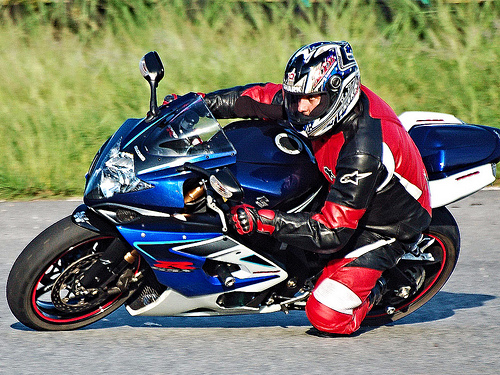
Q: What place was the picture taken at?
A: It was taken at the road.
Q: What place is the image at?
A: It is at the road.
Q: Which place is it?
A: It is a road.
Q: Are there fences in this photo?
A: No, there are no fences.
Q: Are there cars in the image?
A: No, there are no cars.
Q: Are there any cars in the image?
A: No, there are no cars.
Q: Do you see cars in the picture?
A: No, there are no cars.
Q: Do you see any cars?
A: No, there are no cars.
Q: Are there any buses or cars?
A: No, there are no cars or buses.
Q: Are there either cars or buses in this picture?
A: No, there are no cars or buses.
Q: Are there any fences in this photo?
A: No, there are no fences.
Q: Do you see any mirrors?
A: Yes, there is a mirror.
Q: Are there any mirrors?
A: Yes, there is a mirror.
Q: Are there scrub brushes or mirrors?
A: Yes, there is a mirror.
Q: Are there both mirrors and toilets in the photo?
A: No, there is a mirror but no toilets.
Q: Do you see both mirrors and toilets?
A: No, there is a mirror but no toilets.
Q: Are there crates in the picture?
A: No, there are no crates.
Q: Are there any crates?
A: No, there are no crates.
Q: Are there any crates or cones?
A: No, there are no crates or cones.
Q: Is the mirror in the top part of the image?
A: Yes, the mirror is in the top of the image.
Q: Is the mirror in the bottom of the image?
A: No, the mirror is in the top of the image.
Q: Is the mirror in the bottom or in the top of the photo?
A: The mirror is in the top of the image.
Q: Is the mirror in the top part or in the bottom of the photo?
A: The mirror is in the top of the image.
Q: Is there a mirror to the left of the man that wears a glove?
A: Yes, there is a mirror to the left of the man.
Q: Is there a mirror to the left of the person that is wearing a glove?
A: Yes, there is a mirror to the left of the man.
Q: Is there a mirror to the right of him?
A: No, the mirror is to the left of the man.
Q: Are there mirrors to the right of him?
A: No, the mirror is to the left of the man.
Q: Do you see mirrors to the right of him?
A: No, the mirror is to the left of the man.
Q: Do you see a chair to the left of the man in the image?
A: No, there is a mirror to the left of the man.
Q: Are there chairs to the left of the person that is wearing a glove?
A: No, there is a mirror to the left of the man.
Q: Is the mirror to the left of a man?
A: Yes, the mirror is to the left of a man.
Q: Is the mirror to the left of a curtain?
A: No, the mirror is to the left of a man.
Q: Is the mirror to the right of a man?
A: No, the mirror is to the left of a man.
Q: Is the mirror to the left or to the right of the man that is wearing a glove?
A: The mirror is to the left of the man.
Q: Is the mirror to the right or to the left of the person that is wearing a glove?
A: The mirror is to the left of the man.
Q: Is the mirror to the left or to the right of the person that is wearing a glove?
A: The mirror is to the left of the man.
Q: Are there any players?
A: No, there are no players.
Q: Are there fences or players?
A: No, there are no players or fences.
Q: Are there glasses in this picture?
A: No, there are no glasses.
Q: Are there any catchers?
A: No, there are no catchers.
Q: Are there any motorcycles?
A: Yes, there is a motorcycle.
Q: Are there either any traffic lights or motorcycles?
A: Yes, there is a motorcycle.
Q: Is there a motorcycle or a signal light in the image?
A: Yes, there is a motorcycle.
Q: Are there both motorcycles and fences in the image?
A: No, there is a motorcycle but no fences.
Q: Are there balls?
A: No, there are no balls.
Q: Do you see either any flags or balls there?
A: No, there are no balls or flags.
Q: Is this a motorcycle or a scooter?
A: This is a motorcycle.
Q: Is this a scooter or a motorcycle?
A: This is a motorcycle.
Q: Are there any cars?
A: No, there are no cars.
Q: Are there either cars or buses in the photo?
A: No, there are no cars or buses.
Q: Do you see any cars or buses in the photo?
A: No, there are no cars or buses.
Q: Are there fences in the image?
A: No, there are no fences.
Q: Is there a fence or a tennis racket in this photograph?
A: No, there are no fences or rackets.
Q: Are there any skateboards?
A: No, there are no skateboards.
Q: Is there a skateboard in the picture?
A: No, there are no skateboards.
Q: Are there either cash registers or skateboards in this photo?
A: No, there are no skateboards or cash registers.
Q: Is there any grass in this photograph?
A: Yes, there is grass.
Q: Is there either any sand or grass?
A: Yes, there is grass.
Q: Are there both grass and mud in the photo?
A: No, there is grass but no mud.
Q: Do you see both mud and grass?
A: No, there is grass but no mud.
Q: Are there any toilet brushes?
A: No, there are no toilet brushes.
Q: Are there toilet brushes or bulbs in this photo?
A: No, there are no toilet brushes or bulbs.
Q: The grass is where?
A: The grass is on the ground.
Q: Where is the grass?
A: The grass is on the ground.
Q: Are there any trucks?
A: No, there are no trucks.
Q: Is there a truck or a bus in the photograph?
A: No, there are no trucks or buses.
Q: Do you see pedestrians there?
A: No, there are no pedestrians.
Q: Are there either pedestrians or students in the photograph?
A: No, there are no pedestrians or students.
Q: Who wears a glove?
A: The man wears a glove.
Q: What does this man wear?
A: The man wears a glove.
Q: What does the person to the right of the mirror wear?
A: The man wears a glove.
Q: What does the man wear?
A: The man wears a glove.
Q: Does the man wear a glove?
A: Yes, the man wears a glove.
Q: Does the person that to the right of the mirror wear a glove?
A: Yes, the man wears a glove.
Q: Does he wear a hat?
A: No, the man wears a glove.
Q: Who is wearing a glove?
A: The man is wearing a glove.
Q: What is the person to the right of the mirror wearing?
A: The man is wearing a glove.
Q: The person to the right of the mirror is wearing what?
A: The man is wearing a glove.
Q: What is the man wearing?
A: The man is wearing a glove.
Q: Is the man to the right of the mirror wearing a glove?
A: Yes, the man is wearing a glove.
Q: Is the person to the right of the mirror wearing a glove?
A: Yes, the man is wearing a glove.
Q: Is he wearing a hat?
A: No, the man is wearing a glove.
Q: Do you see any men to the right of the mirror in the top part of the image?
A: Yes, there is a man to the right of the mirror.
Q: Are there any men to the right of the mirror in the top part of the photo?
A: Yes, there is a man to the right of the mirror.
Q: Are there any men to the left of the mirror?
A: No, the man is to the right of the mirror.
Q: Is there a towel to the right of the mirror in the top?
A: No, there is a man to the right of the mirror.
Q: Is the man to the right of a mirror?
A: Yes, the man is to the right of a mirror.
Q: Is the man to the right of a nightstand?
A: No, the man is to the right of a mirror.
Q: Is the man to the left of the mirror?
A: No, the man is to the right of the mirror.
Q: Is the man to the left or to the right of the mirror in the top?
A: The man is to the right of the mirror.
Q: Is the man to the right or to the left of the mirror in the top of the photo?
A: The man is to the right of the mirror.